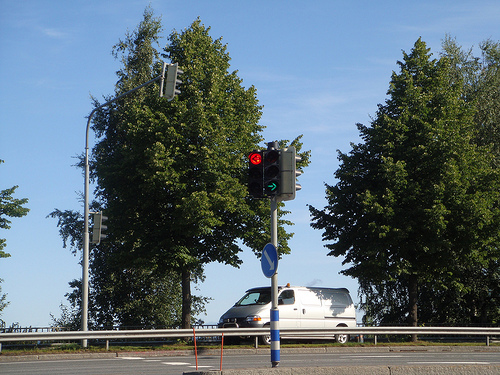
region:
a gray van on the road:
[222, 274, 360, 351]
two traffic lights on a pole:
[240, 132, 305, 372]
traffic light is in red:
[242, 138, 270, 189]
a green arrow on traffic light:
[260, 177, 280, 195]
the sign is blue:
[250, 235, 280, 281]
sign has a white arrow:
[251, 240, 281, 280]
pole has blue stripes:
[260, 202, 285, 363]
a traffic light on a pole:
[65, 51, 195, 158]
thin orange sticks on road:
[187, 321, 204, 371]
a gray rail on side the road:
[3, 318, 499, 357]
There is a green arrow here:
[267, 176, 280, 199]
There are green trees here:
[414, 144, 437, 199]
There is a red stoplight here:
[247, 145, 262, 182]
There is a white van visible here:
[295, 274, 315, 319]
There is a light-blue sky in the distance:
[313, 30, 332, 99]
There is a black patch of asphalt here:
[131, 358, 133, 365]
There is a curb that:
[321, 359, 327, 372]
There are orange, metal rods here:
[220, 335, 232, 361]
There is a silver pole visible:
[86, 143, 106, 226]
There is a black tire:
[263, 319, 275, 348]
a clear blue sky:
[18, 105, 65, 138]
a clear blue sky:
[33, 145, 65, 151]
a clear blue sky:
[61, 173, 76, 196]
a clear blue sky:
[24, 245, 63, 277]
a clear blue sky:
[25, 285, 55, 305]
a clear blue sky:
[331, 58, 361, 92]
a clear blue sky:
[273, 45, 300, 67]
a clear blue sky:
[272, 80, 304, 107]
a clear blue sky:
[316, 112, 338, 137]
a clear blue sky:
[298, 256, 323, 266]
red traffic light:
[241, 147, 266, 168]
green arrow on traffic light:
[261, 178, 283, 194]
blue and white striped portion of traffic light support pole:
[263, 306, 291, 366]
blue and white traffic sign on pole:
[251, 237, 289, 279]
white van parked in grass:
[216, 278, 363, 350]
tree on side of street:
[49, 4, 318, 342]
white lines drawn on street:
[117, 349, 214, 374]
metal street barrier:
[2, 319, 497, 348]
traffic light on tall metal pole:
[78, 57, 188, 347]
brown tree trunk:
[177, 273, 201, 337]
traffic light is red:
[225, 145, 273, 206]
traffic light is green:
[260, 172, 274, 204]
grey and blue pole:
[261, 178, 299, 359]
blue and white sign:
[250, 237, 288, 277]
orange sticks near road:
[182, 322, 259, 371]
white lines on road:
[122, 322, 179, 374]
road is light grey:
[82, 318, 172, 374]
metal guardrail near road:
[1, 309, 445, 362]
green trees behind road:
[73, 57, 483, 309]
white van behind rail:
[211, 275, 393, 351]